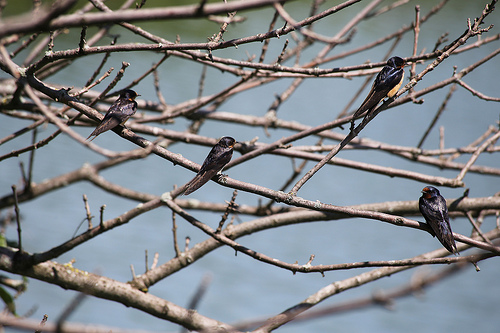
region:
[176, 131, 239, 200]
small dark colored bird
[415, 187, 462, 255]
small dark colored bird with red on its face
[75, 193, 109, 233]
two smaller twigs coming off of a branch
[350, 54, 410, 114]
small dark bird with tan underbelly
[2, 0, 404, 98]
small thin branches of a tree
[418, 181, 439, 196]
dark colored head of a bird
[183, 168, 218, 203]
brownish colored tail end of a bird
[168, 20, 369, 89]
thin branches of a tree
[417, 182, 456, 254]
small dark colored bird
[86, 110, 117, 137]
tail end of a bird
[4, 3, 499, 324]
outdoor daytime nature scene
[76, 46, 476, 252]
four black birds in tree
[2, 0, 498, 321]
clear blue daytime sky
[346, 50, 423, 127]
black bird with yellow breast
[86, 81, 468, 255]
three black birds with orange beaks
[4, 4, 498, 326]
bare brown wooden tree branches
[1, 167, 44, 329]
green leaves on bare brown branches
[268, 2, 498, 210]
bird with yellow chest perched on brown branch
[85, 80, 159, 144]
black bird perched on branch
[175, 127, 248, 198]
black bird with long tail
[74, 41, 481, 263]
Four birds are in the photo.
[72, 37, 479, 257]
The birds are on branches.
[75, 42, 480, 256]
The birds are black.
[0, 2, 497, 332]
The branches crisscross each other.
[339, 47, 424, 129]
The bird is black and orange.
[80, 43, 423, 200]
Three birds are facing right.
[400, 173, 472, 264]
One bird is facing left.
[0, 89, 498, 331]
A blue background is behind the branches.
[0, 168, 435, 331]
The branches are bare.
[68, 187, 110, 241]
The branches have smaller branches and buds.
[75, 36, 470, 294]
birds sitting in branches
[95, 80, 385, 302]
long and leafless branches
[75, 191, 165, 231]
short twigs growing out from branch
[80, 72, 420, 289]
branches crisscrossing each other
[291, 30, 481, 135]
black bird with orange breast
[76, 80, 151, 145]
perched bird with small orange marking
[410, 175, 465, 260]
long tail feathers split apart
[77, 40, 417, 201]
birds facing in the same direction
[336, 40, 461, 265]
one bird higher than the other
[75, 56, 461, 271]
blue background behind wall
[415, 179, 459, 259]
Little dark bird sitting on a branch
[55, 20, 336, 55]
Thin tree branch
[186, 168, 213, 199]
Tail end of a bird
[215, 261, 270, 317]
blue sky through the branches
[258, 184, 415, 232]
Two branches of a tree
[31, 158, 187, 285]
various branches of a tree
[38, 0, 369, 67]
long thin tree branch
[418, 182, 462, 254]
Small dark bird with red on its face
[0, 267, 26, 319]
two green leaves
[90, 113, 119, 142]
tail feathers on a bird